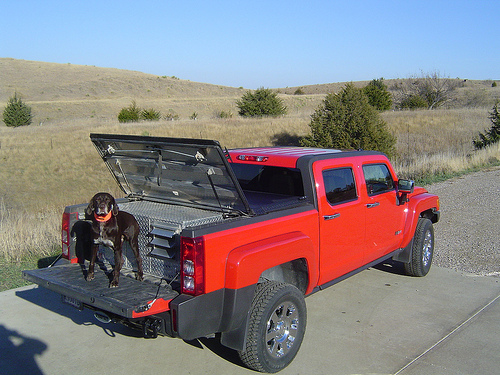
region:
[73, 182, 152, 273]
black dog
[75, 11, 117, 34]
white clouds in blue sky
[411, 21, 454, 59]
white clouds in blue sky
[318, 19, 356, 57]
white clouds in blue sky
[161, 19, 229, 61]
white clouds in blue sky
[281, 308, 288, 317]
silver spoke on rim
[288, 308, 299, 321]
silver spoke on rim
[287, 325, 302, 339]
silver spoke on rim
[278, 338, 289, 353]
silver spoke on rim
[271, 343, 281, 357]
silver spoke on rim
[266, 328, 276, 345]
silver spoke on rim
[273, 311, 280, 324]
silver spoke on rim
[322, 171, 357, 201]
glass window on truck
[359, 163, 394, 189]
glass window on truck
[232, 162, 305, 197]
glass window on truck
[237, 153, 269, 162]
Brake light on the back of a truck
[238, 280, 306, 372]
Rear wheel on a red truck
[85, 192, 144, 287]
Black dog in a truck bed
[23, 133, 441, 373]
A red truck with a dog on the back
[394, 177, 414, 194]
Side mirror on a red truck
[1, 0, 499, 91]
Blue sky without any clouds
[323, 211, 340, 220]
Handle on the side of a car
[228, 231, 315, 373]
Rear fender and wheel of a truck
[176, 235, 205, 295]
Tail light of a red truck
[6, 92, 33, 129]
Green bush surrounded by brown grass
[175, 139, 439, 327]
red truck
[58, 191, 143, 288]
black dog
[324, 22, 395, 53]
white clouds in blue sky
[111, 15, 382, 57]
Sky is blue color.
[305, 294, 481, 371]
Road is grey color.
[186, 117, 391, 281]
Car is red color.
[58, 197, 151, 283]
Dog is red color.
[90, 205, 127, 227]
Dog collar is red color.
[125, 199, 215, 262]
Box is grey color.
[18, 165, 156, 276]
Dog is standing in the car.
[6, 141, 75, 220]
Grass is brown color.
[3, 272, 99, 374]
Shadow falls on road.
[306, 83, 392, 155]
Bushes are green color.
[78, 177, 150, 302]
a black and white dog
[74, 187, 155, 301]
a dog on the tailgate of a vehicle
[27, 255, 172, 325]
a tail gate on a vehicle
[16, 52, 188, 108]
a hillside covered with straw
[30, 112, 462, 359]
a parked red vehicle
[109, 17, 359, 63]
a clear blue sky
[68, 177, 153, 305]
a dog on the back of a truck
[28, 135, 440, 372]
a red pickup truck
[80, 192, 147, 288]
a large black dog in truck bed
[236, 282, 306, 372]
a truck's rear tire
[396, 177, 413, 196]
a truck's sideview mirror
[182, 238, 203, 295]
a truck's rear tail light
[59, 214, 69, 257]
a truck's rear tail light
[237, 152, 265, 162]
a truck's rear tail light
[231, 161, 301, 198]
a truck's rear window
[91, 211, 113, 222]
a red dog collar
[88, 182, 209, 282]
silver bin in the pick up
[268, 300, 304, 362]
chrome rim on the truck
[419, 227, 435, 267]
chrome rim on the truck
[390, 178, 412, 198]
mirror on the truck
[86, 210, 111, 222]
truck wearing a red bandanna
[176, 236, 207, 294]
red light on the pick up truck